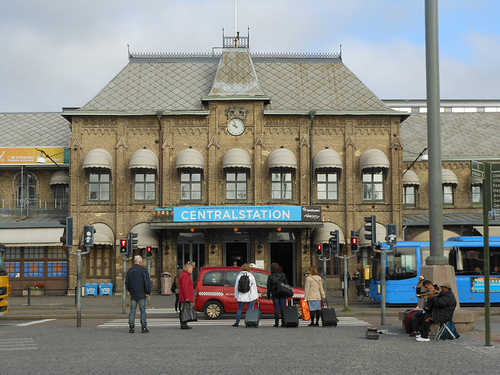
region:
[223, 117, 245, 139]
clock on front of building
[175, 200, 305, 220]
central station sign on building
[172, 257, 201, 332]
person waiting for bus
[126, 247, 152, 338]
person waiting for bus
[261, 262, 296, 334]
person waiting for bus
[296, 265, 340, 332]
person waiting for bus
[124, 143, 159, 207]
window with awning on building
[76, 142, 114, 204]
window with awning on building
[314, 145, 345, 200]
window with awning on building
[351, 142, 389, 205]
window with awning on building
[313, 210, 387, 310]
a traffic light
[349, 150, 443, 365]
a traffic light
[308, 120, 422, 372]
a traffic light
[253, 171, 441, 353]
a traffic light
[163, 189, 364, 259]
central station sign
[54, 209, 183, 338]
people crossing traffic light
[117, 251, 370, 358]
people waiting to cross the street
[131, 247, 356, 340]
5 people crossing the street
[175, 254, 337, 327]
red van on the crosswalk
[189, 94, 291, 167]
clock on a building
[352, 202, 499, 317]
blue bus near the building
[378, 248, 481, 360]
a couple of people sitting next to a pole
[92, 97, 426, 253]
building with many windows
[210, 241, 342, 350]
three women carrying suitcases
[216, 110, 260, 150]
clock on building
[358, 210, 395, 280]
traffic light on pole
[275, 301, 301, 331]
black suitcase on wheels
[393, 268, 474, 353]
people sitting in chairs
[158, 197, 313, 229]
blue and white central station sign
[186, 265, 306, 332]
red car parked on street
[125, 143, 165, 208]
window in building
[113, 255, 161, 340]
man in black jacket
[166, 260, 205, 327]
person in a red jacket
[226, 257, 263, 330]
person wearing white jacket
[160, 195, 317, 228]
A blue sign with white lettering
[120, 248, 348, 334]
pedestrians waiting for transportation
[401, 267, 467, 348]
a man sitting playing an instrument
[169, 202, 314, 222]
A central station sign terminal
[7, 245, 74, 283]
colorful glass windows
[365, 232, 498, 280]
The top of a blue bus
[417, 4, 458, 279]
a metal pole on a cement block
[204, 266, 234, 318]
The back side of a red car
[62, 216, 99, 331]
changing light post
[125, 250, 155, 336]
A man with white hair, black shirt and pants with his back to the camera